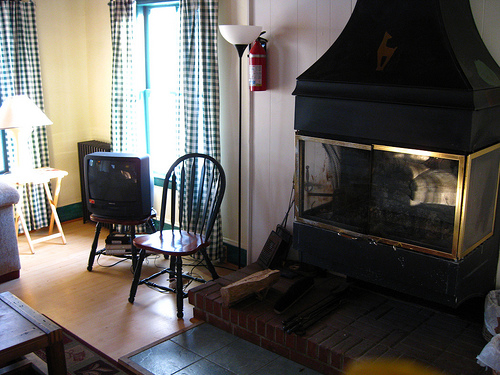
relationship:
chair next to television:
[127, 151, 225, 320] [83, 152, 154, 218]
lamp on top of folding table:
[0, 94, 56, 184] [0, 167, 70, 255]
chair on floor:
[127, 151, 225, 320] [0, 214, 246, 363]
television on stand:
[83, 152, 154, 218] [87, 211, 169, 271]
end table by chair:
[0, 165, 71, 255] [0, 179, 25, 286]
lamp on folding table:
[0, 94, 56, 184] [0, 167, 70, 255]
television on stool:
[85, 151, 156, 218] [83, 212, 161, 272]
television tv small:
[83, 152, 154, 218] [97, 173, 129, 213]